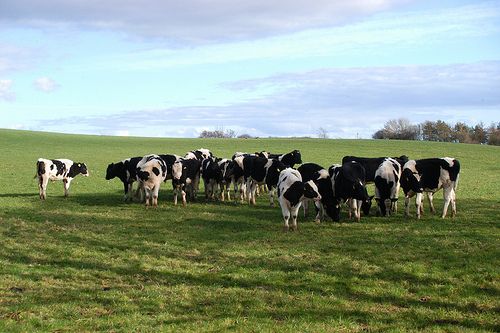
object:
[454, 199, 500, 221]
shadows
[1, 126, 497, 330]
grass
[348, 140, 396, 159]
floor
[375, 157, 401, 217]
cow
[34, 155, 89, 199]
cow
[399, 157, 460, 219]
cow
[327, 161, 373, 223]
cow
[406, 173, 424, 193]
head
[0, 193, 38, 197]
shadow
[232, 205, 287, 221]
shadow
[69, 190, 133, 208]
shadow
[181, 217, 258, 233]
shadow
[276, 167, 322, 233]
cow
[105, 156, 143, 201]
cow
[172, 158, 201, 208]
cow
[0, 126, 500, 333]
field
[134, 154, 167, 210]
cow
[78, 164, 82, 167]
tag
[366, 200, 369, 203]
tag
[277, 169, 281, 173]
tag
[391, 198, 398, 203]
ear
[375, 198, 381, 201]
ear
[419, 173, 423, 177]
ear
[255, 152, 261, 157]
ear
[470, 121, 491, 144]
trees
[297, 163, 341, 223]
cow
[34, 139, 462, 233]
cattle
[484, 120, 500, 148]
trees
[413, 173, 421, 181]
spot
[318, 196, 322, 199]
nose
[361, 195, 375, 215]
head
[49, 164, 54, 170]
spot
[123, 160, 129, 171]
spot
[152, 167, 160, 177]
spot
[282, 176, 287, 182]
spot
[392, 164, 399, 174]
spot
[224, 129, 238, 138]
tree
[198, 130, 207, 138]
tree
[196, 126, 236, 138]
group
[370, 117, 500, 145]
group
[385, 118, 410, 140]
tree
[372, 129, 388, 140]
tree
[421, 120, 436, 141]
tree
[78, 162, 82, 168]
ear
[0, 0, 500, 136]
sky